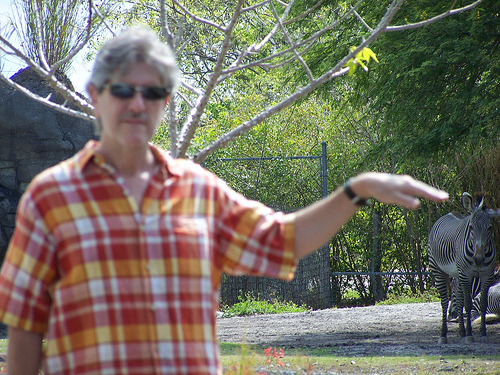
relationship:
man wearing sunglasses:
[0, 30, 452, 374] [106, 73, 173, 108]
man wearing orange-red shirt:
[0, 30, 452, 374] [1, 140, 298, 374]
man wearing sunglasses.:
[0, 30, 452, 374] [107, 81, 179, 103]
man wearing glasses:
[0, 30, 452, 374] [105, 78, 175, 103]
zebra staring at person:
[427, 192, 500, 344] [71, 61, 275, 342]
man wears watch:
[0, 30, 452, 374] [343, 182, 367, 206]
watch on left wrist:
[343, 182, 367, 206] [348, 172, 375, 203]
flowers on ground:
[262, 345, 283, 369] [287, 310, 424, 367]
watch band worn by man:
[342, 182, 365, 209] [0, 30, 452, 374]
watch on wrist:
[337, 179, 367, 211] [337, 159, 391, 215]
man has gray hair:
[0, 30, 452, 374] [83, 21, 185, 85]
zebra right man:
[427, 192, 500, 344] [36, 17, 465, 303]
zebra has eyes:
[427, 192, 500, 344] [462, 217, 498, 229]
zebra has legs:
[427, 192, 500, 344] [432, 270, 482, 339]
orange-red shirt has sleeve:
[1, 140, 298, 374] [1, 190, 57, 333]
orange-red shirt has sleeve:
[1, 140, 298, 374] [215, 171, 294, 281]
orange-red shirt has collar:
[1, 140, 298, 374] [76, 136, 184, 183]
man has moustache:
[0, 30, 452, 374] [86, 32, 181, 156]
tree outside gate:
[362, 198, 394, 271] [332, 266, 429, 308]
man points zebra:
[67, 13, 340, 282] [419, 195, 497, 358]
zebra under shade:
[427, 192, 500, 344] [392, 148, 499, 357]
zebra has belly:
[423, 153, 499, 345] [437, 257, 458, 273]